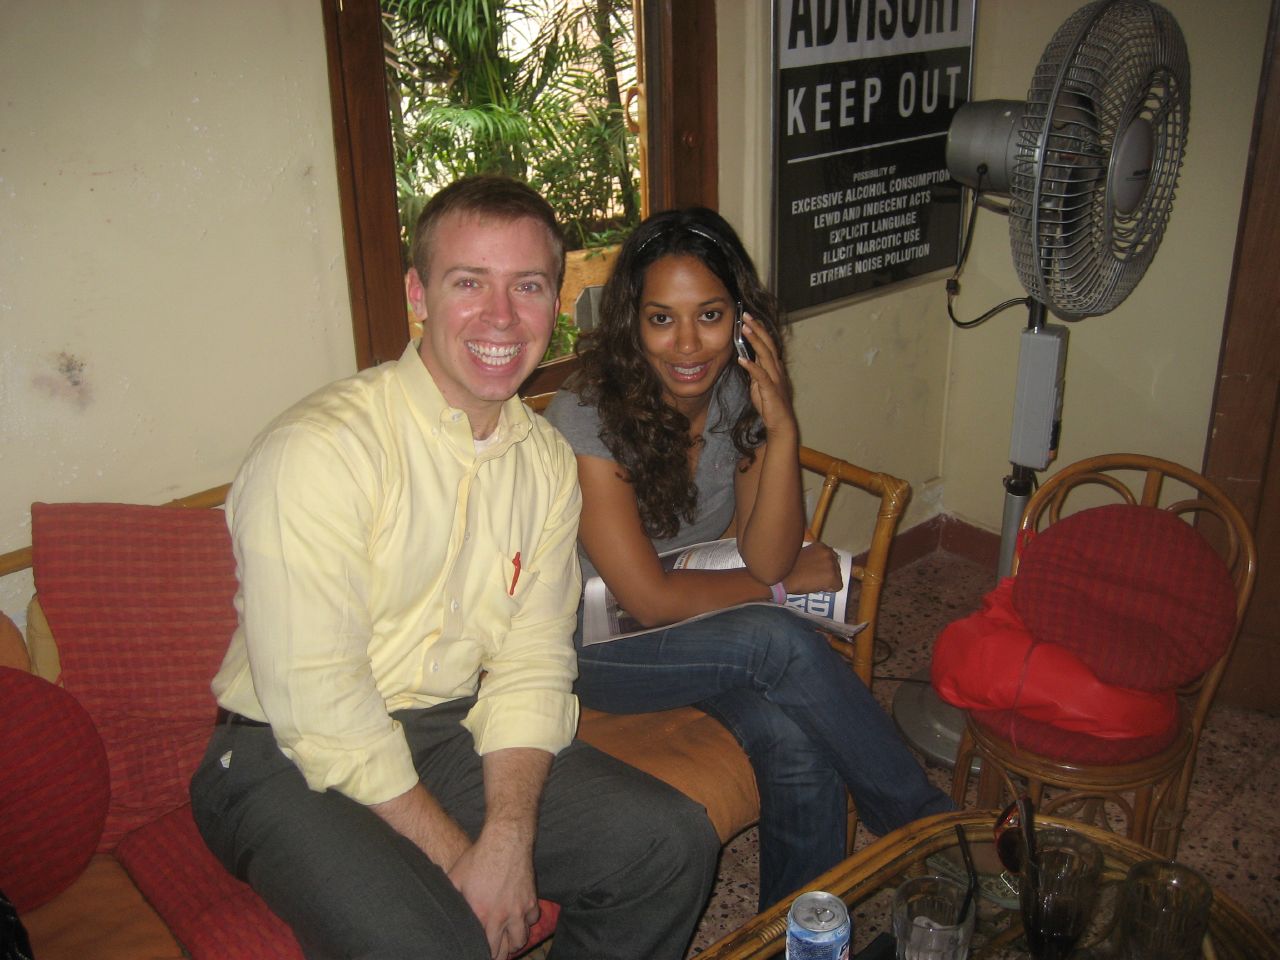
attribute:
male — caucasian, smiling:
[187, 158, 773, 960]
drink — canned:
[762, 889, 892, 960]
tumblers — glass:
[925, 742, 1143, 932]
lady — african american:
[564, 209, 985, 907]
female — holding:
[587, 202, 1008, 939]